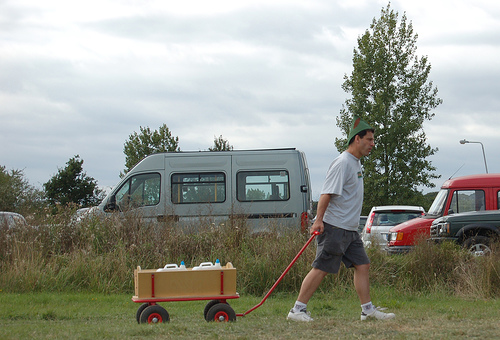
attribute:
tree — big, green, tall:
[330, 12, 429, 213]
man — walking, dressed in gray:
[286, 120, 382, 313]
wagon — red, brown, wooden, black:
[125, 262, 289, 321]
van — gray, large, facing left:
[73, 153, 345, 243]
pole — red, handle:
[237, 236, 319, 284]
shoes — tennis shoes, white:
[297, 301, 407, 333]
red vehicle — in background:
[391, 184, 500, 258]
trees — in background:
[6, 158, 137, 211]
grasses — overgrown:
[38, 229, 112, 290]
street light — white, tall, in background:
[460, 127, 491, 172]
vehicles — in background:
[366, 172, 499, 290]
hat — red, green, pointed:
[344, 118, 376, 133]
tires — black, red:
[129, 306, 243, 322]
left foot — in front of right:
[355, 294, 406, 339]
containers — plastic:
[147, 255, 257, 266]